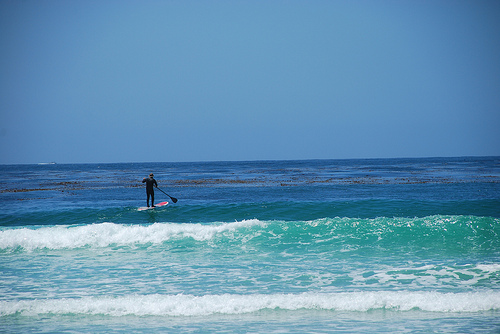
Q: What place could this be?
A: It is an ocean.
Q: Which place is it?
A: It is an ocean.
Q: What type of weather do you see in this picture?
A: It is clear.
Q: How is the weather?
A: It is clear.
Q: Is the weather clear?
A: Yes, it is clear.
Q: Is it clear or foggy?
A: It is clear.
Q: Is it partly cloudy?
A: No, it is clear.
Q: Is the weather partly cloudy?
A: No, it is clear.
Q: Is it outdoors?
A: Yes, it is outdoors.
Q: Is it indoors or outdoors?
A: It is outdoors.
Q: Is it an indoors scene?
A: No, it is outdoors.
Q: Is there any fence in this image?
A: No, there are no fences.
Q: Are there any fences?
A: No, there are no fences.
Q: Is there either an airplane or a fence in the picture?
A: No, there are no fences or airplanes.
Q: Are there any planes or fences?
A: No, there are no fences or planes.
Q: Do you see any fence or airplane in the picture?
A: No, there are no fences or airplanes.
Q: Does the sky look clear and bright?
A: Yes, the sky is clear and bright.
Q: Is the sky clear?
A: Yes, the sky is clear.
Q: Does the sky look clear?
A: Yes, the sky is clear.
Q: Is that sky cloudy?
A: No, the sky is clear.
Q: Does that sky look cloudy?
A: No, the sky is clear.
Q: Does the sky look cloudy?
A: No, the sky is clear.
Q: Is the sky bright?
A: Yes, the sky is bright.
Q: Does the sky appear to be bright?
A: Yes, the sky is bright.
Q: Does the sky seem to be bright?
A: Yes, the sky is bright.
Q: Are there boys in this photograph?
A: No, there are no boys.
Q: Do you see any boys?
A: No, there are no boys.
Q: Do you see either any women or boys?
A: No, there are no boys or women.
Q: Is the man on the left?
A: Yes, the man is on the left of the image.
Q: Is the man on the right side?
A: No, the man is on the left of the image.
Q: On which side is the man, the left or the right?
A: The man is on the left of the image.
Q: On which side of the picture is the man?
A: The man is on the left of the image.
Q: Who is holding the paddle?
A: The man is holding the paddle.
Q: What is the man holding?
A: The man is holding the oar.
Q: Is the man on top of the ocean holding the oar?
A: Yes, the man is holding the oar.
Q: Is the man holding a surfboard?
A: No, the man is holding the oar.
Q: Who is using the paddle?
A: The man is using the paddle.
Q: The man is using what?
A: The man is using a paddle.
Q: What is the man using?
A: The man is using a paddle.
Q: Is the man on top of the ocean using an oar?
A: Yes, the man is using an oar.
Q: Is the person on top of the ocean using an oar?
A: Yes, the man is using an oar.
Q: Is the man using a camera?
A: No, the man is using an oar.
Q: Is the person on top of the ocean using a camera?
A: No, the man is using an oar.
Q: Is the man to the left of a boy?
A: No, the man is to the left of the paddle.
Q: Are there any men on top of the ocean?
A: Yes, there is a man on top of the ocean.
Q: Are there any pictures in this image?
A: No, there are no pictures.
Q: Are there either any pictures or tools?
A: No, there are no pictures or tools.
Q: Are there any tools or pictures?
A: No, there are no pictures or tools.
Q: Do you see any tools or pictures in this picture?
A: No, there are no pictures or tools.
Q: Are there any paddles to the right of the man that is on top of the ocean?
A: Yes, there is a paddle to the right of the man.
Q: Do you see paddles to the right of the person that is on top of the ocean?
A: Yes, there is a paddle to the right of the man.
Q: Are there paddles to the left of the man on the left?
A: No, the paddle is to the right of the man.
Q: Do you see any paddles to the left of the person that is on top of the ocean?
A: No, the paddle is to the right of the man.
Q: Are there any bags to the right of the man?
A: No, there is a paddle to the right of the man.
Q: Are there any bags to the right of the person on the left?
A: No, there is a paddle to the right of the man.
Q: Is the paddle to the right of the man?
A: Yes, the paddle is to the right of the man.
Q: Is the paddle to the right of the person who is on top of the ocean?
A: Yes, the paddle is to the right of the man.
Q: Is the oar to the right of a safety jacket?
A: No, the oar is to the right of the man.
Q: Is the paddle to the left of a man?
A: No, the paddle is to the right of a man.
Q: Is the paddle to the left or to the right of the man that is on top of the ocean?
A: The paddle is to the right of the man.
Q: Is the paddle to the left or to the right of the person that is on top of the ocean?
A: The paddle is to the right of the man.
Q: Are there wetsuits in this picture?
A: Yes, there is a wetsuit.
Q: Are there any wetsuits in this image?
A: Yes, there is a wetsuit.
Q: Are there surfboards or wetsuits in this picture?
A: Yes, there is a wetsuit.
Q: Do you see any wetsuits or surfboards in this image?
A: Yes, there is a wetsuit.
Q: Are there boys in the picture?
A: No, there are no boys.